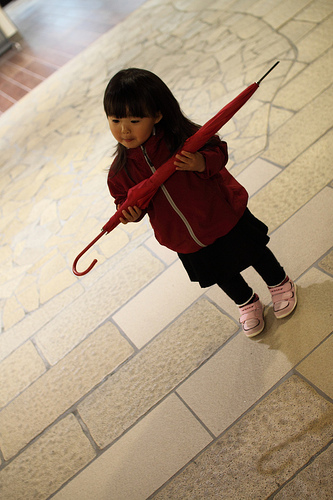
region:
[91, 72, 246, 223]
red unfolded umbrella in hands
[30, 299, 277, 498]
brick style tiles on ground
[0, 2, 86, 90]
red brick tile in background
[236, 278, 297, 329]
pink velcro sneakers on girl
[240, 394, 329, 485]
hook shaped stain on floor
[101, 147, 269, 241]
red hoodie on little girl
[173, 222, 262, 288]
black skirt on little girl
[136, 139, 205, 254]
white zipper on red hoodie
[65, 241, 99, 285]
red umbrella hook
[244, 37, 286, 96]
point on the end of umbrella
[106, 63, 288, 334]
little girl holding red umbrella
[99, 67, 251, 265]
girl wearing a red jacket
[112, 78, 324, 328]
girl wearing a pink shoes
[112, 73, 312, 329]
girl wearing a black skirt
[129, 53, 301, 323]
girl wearing pink shoes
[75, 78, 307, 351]
girl standing on a tile floor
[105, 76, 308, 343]
girl wearing black tights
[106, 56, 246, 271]
girl red jacket zipped up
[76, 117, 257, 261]
red umbrella with a handle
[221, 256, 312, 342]
pink shoes with no laces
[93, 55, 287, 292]
a little girl holding a umbrella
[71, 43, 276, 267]
a little girl holding a red umbrella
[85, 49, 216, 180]
a little girl with black hair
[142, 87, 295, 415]
a little girl wearing pink shoes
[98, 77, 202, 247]
a little girl wearing a red jacket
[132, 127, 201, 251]
a red jacket with a white zipper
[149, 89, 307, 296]
a little girl wearing a black skirt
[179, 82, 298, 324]
a little girl wearing black leggins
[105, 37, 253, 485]
a little girl standing and holding a umbrella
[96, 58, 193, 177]
a little girl with long black hair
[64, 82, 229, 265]
the umbrella is red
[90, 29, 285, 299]
the umbrella is red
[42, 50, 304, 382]
a young girl holding an umbrella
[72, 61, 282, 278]
a red umbrella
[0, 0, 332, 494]
white and tan tiled floor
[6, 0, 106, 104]
some brown tiled floor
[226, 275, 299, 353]
pink shoes on the girl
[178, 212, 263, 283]
a black skirt on the girl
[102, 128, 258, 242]
a red jacket on the girl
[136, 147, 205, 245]
the zipper on the jacket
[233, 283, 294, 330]
Velcro straps on the shoes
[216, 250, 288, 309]
black socks on the girl